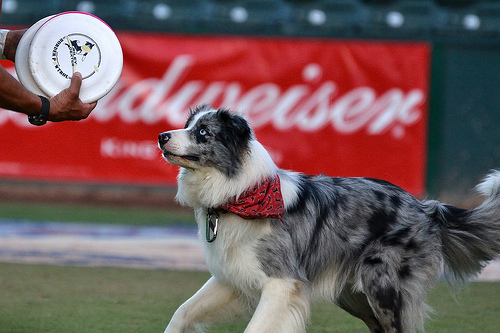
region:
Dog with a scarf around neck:
[116, 99, 306, 247]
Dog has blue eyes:
[123, 87, 255, 182]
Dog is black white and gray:
[136, 99, 386, 323]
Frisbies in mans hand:
[18, 10, 118, 112]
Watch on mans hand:
[22, 85, 74, 150]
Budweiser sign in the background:
[75, 33, 425, 168]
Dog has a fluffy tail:
[420, 156, 498, 302]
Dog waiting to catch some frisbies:
[41, 34, 441, 309]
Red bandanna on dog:
[175, 117, 290, 232]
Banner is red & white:
[246, 39, 443, 159]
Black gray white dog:
[145, 103, 499, 332]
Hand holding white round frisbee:
[31, 68, 101, 125]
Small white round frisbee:
[30, 9, 122, 101]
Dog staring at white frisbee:
[150, 97, 497, 332]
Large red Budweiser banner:
[0, 22, 427, 208]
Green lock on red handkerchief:
[202, 205, 219, 243]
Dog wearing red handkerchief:
[149, 97, 499, 332]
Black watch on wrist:
[25, 95, 54, 125]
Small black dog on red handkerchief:
[272, 184, 282, 194]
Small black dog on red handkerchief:
[264, 203, 275, 211]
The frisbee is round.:
[26, 7, 127, 104]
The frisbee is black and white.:
[26, 7, 123, 106]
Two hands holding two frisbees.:
[1, 5, 128, 130]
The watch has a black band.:
[21, 86, 59, 129]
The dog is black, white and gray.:
[151, 98, 498, 332]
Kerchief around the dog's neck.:
[155, 98, 295, 242]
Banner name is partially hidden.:
[0, 20, 440, 210]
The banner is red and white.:
[0, 19, 431, 203]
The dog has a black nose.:
[152, 103, 246, 173]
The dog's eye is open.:
[156, 100, 258, 177]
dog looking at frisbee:
[140, 105, 497, 331]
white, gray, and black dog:
[152, 101, 499, 327]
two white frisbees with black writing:
[17, 7, 123, 102]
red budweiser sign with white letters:
[2, 21, 425, 209]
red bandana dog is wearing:
[209, 176, 290, 226]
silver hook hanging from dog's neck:
[197, 211, 224, 248]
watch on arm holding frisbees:
[25, 93, 52, 126]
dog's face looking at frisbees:
[15, 8, 248, 181]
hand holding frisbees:
[41, 70, 96, 121]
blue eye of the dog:
[196, 120, 212, 136]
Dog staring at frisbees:
[142, 94, 498, 331]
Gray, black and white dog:
[147, 97, 499, 332]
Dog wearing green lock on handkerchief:
[151, 105, 498, 332]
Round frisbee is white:
[27, 10, 125, 108]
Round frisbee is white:
[15, 12, 73, 102]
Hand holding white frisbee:
[22, 70, 100, 127]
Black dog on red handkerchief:
[271, 190, 283, 205]